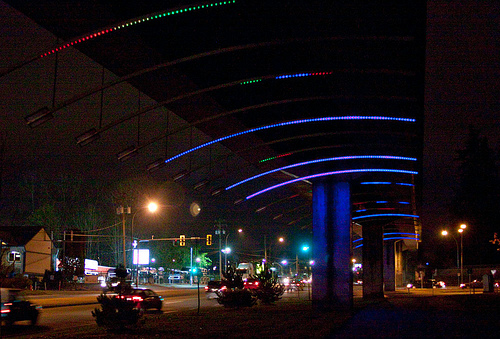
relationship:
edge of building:
[32, 213, 62, 236] [8, 217, 65, 292]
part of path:
[424, 274, 452, 295] [366, 294, 426, 331]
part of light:
[384, 147, 405, 172] [164, 108, 424, 187]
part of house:
[14, 233, 55, 272] [8, 217, 65, 292]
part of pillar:
[326, 199, 346, 235] [305, 156, 368, 304]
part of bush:
[182, 251, 189, 262] [165, 246, 209, 270]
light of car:
[164, 108, 424, 187] [167, 249, 307, 310]